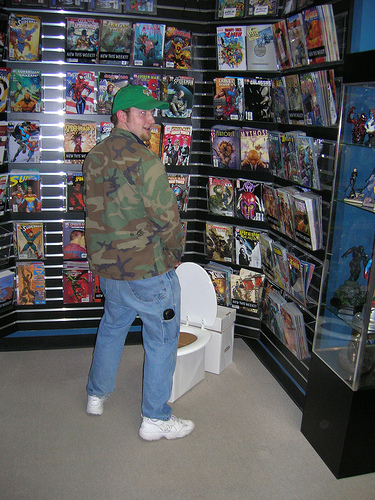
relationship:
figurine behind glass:
[331, 245, 371, 313] [304, 87, 374, 382]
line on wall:
[7, 324, 148, 336] [6, 3, 213, 352]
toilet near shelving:
[168, 261, 219, 405] [0, 7, 349, 395]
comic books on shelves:
[187, 19, 359, 244] [207, 6, 332, 356]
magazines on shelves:
[206, 10, 324, 346] [207, 6, 332, 356]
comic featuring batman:
[2, 117, 44, 166] [10, 124, 29, 160]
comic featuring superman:
[2, 117, 44, 166] [26, 121, 39, 158]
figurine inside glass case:
[328, 240, 368, 313] [313, 72, 373, 317]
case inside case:
[144, 305, 190, 337] [162, 308, 179, 345]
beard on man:
[140, 133, 150, 141] [110, 92, 166, 163]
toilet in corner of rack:
[155, 261, 256, 405] [243, 276, 358, 374]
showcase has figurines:
[320, 161, 374, 369] [342, 235, 364, 331]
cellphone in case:
[163, 307, 174, 318] [162, 308, 179, 345]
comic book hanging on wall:
[19, 212, 61, 266] [215, 20, 332, 343]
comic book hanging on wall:
[209, 126, 240, 167] [0, 8, 218, 335]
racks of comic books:
[4, 3, 337, 368] [277, 0, 343, 68]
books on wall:
[252, 22, 349, 129] [1, 5, 243, 343]